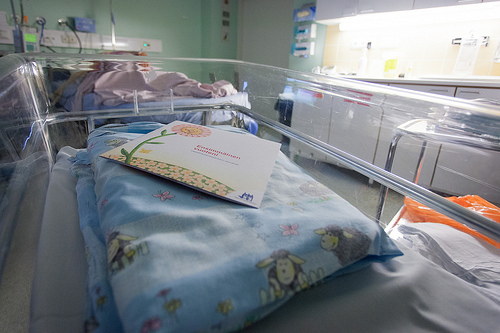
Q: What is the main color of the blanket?
A: Blue.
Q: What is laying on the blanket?
A: An envelope.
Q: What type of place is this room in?
A: Hospital.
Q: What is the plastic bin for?
A: A newborn baby.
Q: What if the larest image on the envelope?
A: A flower.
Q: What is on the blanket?
A: Card.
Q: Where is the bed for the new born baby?
A: Bassinet.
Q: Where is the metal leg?
A: Tray table.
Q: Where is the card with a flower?
A: On bed.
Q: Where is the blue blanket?
A: On bed.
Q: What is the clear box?
A: Bassinet.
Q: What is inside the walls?
A: Cabinets.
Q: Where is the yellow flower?
A: On card.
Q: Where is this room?
A: Hospital.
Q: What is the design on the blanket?
A: Sheep design.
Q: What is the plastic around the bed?
A: A plastic baby incubator.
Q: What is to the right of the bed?
A: A set of white cabinets.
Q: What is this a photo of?
A: Incubator.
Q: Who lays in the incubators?
A: Babies.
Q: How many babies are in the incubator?
A: None.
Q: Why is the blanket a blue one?
A: Baby is a boy.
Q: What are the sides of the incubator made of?
A: Clear plastic.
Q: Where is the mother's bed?
A: Behind the incubator.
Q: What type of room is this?
A: Hospital room.